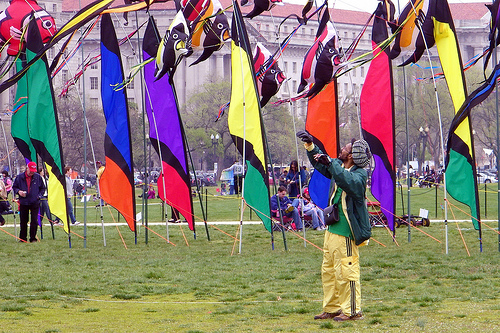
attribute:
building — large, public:
[1, 1, 499, 121]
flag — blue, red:
[93, 12, 140, 234]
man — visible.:
[284, 153, 309, 201]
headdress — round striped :
[350, 135, 372, 167]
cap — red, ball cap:
[24, 160, 37, 170]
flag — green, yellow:
[24, 7, 72, 247]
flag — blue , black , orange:
[86, 8, 140, 249]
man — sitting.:
[268, 189, 302, 226]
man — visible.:
[250, 103, 407, 331]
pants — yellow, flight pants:
[322, 228, 364, 314]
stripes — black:
[345, 233, 357, 315]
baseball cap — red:
[26, 160, 38, 173]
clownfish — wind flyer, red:
[0, 2, 60, 69]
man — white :
[273, 181, 305, 235]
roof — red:
[331, 2, 338, 12]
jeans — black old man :
[14, 197, 41, 244]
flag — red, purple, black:
[34, 41, 498, 244]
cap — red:
[22, 164, 39, 174]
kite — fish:
[164, 8, 221, 48]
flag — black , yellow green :
[396, 0, 484, 256]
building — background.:
[8, 0, 498, 161]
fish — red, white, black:
[2, 0, 59, 65]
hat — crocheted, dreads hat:
[351, 136, 383, 175]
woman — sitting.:
[290, 182, 314, 221]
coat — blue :
[270, 189, 292, 215]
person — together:
[270, 194, 294, 223]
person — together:
[293, 193, 322, 231]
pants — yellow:
[307, 232, 369, 321]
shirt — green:
[300, 142, 376, 242]